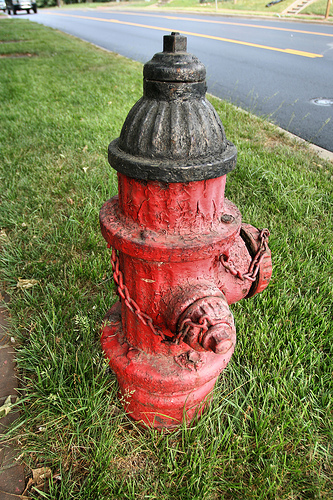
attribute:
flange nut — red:
[200, 319, 239, 359]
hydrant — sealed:
[101, 81, 272, 420]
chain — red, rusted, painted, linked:
[109, 246, 208, 352]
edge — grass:
[264, 131, 304, 171]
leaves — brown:
[12, 259, 76, 361]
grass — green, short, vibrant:
[4, 32, 331, 496]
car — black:
[12, 0, 44, 18]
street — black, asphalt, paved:
[6, 3, 331, 157]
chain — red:
[100, 241, 285, 372]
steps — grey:
[281, 5, 312, 20]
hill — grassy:
[103, 0, 329, 23]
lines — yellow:
[57, 4, 328, 64]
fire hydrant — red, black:
[97, 29, 274, 426]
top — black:
[107, 27, 240, 177]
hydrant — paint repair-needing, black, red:
[78, 29, 274, 426]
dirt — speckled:
[0, 292, 32, 499]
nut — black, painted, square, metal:
[163, 34, 186, 53]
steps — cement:
[278, 0, 316, 16]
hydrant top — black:
[103, 27, 242, 182]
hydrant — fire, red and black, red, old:
[97, 29, 275, 434]